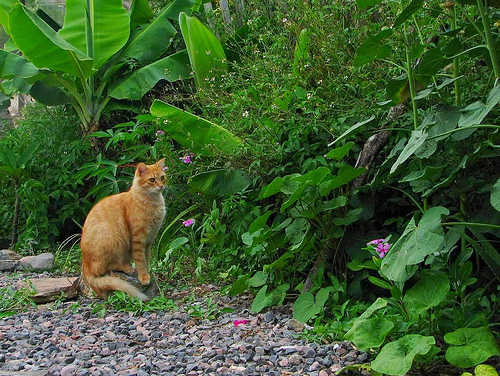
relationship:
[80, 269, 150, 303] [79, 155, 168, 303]
tail of cat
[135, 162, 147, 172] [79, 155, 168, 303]
ear on cat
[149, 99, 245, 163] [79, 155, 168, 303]
leaf behind cat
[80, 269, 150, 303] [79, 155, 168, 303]
tail on cat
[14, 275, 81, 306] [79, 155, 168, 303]
rock behind cat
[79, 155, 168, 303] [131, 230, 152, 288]
cat has leg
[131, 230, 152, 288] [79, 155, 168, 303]
leg on cat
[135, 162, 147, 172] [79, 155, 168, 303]
ear of cat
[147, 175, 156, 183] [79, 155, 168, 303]
eye of cat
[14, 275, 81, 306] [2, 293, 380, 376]
rock on road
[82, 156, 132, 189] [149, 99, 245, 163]
weed behind leaf